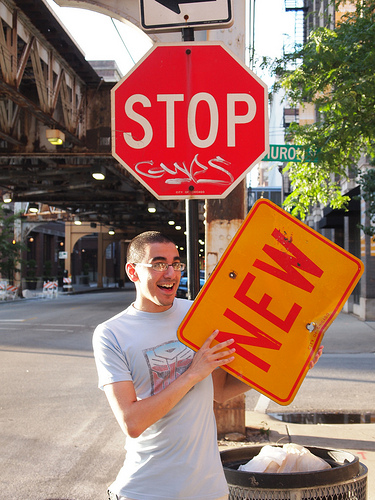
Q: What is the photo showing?
A: It is showing a road.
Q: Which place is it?
A: It is a road.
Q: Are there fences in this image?
A: No, there are no fences.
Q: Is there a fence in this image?
A: No, there are no fences.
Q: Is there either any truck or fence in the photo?
A: No, there are no fences or trucks.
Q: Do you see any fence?
A: No, there are no fences.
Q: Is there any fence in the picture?
A: No, there are no fences.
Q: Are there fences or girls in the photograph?
A: No, there are no fences or girls.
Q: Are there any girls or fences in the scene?
A: No, there are no fences or girls.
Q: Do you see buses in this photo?
A: No, there are no buses.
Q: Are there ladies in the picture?
A: No, there are no ladies.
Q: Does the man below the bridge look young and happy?
A: Yes, the man is young and happy.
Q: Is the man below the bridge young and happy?
A: Yes, the man is young and happy.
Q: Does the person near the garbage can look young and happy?
A: Yes, the man is young and happy.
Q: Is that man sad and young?
A: No, the man is young but happy.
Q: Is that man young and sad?
A: No, the man is young but happy.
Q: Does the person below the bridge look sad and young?
A: No, the man is young but happy.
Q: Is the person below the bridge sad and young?
A: No, the man is young but happy.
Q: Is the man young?
A: Yes, the man is young.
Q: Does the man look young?
A: Yes, the man is young.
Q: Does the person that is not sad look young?
A: Yes, the man is young.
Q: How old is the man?
A: The man is young.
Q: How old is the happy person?
A: The man is young.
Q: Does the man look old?
A: No, the man is young.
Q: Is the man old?
A: No, the man is young.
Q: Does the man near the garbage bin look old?
A: No, the man is young.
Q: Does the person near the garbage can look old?
A: No, the man is young.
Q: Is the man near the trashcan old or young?
A: The man is young.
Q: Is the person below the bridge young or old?
A: The man is young.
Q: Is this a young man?
A: Yes, this is a young man.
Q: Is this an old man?
A: No, this is a young man.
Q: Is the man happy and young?
A: Yes, the man is happy and young.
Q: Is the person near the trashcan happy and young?
A: Yes, the man is happy and young.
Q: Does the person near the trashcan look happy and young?
A: Yes, the man is happy and young.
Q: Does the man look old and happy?
A: No, the man is happy but young.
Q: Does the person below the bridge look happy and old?
A: No, the man is happy but young.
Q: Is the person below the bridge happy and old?
A: No, the man is happy but young.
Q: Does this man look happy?
A: Yes, the man is happy.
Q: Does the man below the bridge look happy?
A: Yes, the man is happy.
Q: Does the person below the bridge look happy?
A: Yes, the man is happy.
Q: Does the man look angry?
A: No, the man is happy.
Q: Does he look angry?
A: No, the man is happy.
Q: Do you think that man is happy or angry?
A: The man is happy.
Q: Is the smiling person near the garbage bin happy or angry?
A: The man is happy.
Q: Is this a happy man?
A: Yes, this is a happy man.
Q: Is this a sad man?
A: No, this is a happy man.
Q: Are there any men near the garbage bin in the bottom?
A: Yes, there is a man near the trash bin.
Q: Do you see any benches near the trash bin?
A: No, there is a man near the trash bin.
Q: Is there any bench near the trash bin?
A: No, there is a man near the trash bin.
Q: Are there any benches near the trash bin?
A: No, there is a man near the trash bin.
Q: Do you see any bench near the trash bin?
A: No, there is a man near the trash bin.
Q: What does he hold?
A: The man holds the sign.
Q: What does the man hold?
A: The man holds the sign.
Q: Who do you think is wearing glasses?
A: The man is wearing glasses.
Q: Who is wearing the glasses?
A: The man is wearing glasses.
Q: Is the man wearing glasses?
A: Yes, the man is wearing glasses.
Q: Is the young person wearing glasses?
A: Yes, the man is wearing glasses.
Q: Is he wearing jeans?
A: No, the man is wearing glasses.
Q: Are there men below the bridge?
A: Yes, there is a man below the bridge.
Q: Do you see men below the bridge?
A: Yes, there is a man below the bridge.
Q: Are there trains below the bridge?
A: No, there is a man below the bridge.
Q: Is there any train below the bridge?
A: No, there is a man below the bridge.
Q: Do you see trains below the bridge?
A: No, there is a man below the bridge.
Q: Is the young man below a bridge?
A: Yes, the man is below a bridge.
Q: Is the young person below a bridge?
A: Yes, the man is below a bridge.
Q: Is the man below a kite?
A: No, the man is below a bridge.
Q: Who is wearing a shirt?
A: The man is wearing a shirt.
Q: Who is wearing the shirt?
A: The man is wearing a shirt.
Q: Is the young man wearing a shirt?
A: Yes, the man is wearing a shirt.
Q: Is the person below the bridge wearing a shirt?
A: Yes, the man is wearing a shirt.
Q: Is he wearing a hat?
A: No, the man is wearing a shirt.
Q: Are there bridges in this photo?
A: Yes, there is a bridge.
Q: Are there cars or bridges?
A: Yes, there is a bridge.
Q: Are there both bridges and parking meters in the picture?
A: No, there is a bridge but no parking meters.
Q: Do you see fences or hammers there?
A: No, there are no fences or hammers.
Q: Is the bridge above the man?
A: Yes, the bridge is above the man.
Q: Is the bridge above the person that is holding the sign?
A: Yes, the bridge is above the man.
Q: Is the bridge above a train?
A: No, the bridge is above the man.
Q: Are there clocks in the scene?
A: No, there are no clocks.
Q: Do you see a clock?
A: No, there are no clocks.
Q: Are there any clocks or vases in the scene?
A: No, there are no clocks or vases.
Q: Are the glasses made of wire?
A: Yes, the glasses are made of wire.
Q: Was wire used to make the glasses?
A: Yes, the glasses are made of wire.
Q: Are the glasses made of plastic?
A: No, the glasses are made of wire.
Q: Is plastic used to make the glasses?
A: No, the glasses are made of wire.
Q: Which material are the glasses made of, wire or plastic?
A: The glasses are made of wire.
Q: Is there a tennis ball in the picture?
A: No, there are no tennis balls.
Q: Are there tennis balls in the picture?
A: No, there are no tennis balls.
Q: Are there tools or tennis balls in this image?
A: No, there are no tennis balls or tools.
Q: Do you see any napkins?
A: No, there are no napkins.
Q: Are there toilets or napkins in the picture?
A: No, there are no napkins or toilets.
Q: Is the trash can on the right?
A: Yes, the trash can is on the right of the image.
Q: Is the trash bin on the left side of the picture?
A: No, the trash bin is on the right of the image.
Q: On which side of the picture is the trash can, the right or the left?
A: The trash can is on the right of the image.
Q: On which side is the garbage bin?
A: The garbage bin is on the right of the image.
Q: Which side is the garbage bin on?
A: The garbage bin is on the right of the image.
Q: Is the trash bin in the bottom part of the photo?
A: Yes, the trash bin is in the bottom of the image.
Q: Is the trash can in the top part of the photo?
A: No, the trash can is in the bottom of the image.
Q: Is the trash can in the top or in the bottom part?
A: The trash can is in the bottom of the image.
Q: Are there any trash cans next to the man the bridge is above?
A: Yes, there is a trash can next to the man.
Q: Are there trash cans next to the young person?
A: Yes, there is a trash can next to the man.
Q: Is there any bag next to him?
A: No, there is a trash can next to the man.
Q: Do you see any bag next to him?
A: No, there is a trash can next to the man.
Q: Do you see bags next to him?
A: No, there is a trash can next to the man.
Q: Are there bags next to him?
A: No, there is a trash can next to the man.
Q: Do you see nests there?
A: No, there are no nests.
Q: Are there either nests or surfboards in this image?
A: No, there are no nests or surfboards.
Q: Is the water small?
A: Yes, the water is small.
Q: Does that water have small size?
A: Yes, the water is small.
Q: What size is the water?
A: The water is small.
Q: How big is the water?
A: The water is small.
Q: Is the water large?
A: No, the water is small.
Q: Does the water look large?
A: No, the water is small.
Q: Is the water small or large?
A: The water is small.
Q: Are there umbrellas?
A: No, there are no umbrellas.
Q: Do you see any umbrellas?
A: No, there are no umbrellas.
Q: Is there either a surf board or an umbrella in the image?
A: No, there are no umbrellas or surfboards.